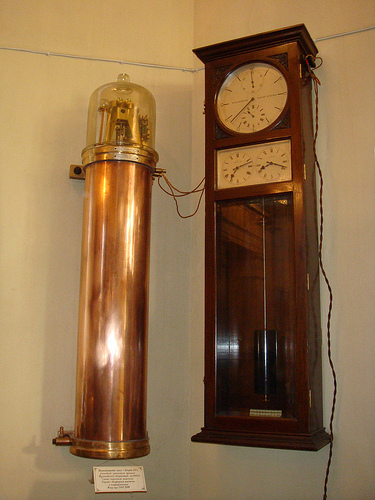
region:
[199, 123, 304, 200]
clock with the roman numeral l on it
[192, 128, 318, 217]
clock with the roman numeral ll on it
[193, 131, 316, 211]
clock with the roman numeral lll on it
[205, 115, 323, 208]
clock with the roman numeral lV on it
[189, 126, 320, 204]
clock with the roman numeral V on it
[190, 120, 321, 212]
clock with the roman numeral Vl on it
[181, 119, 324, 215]
clock with the roman numeral Vll on it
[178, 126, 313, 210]
clock with the roman numeral Vlll on it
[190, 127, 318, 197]
clock with the roman numeral X on it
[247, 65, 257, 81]
black line on device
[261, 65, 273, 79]
black line on device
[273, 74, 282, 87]
black line on device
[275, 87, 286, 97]
black line on device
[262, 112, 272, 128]
black line on device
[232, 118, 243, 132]
black line on device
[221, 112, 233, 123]
black line on device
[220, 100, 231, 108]
black line on device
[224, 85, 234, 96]
black line on device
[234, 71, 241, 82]
black line on device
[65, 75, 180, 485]
a long bronze capsule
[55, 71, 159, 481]
bronze capsule attached to the wall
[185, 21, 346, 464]
an old clock on the wall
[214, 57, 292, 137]
clock is color white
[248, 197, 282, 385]
pendule of the clock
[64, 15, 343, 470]
a machine next a clock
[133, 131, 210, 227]
wires connecting a clock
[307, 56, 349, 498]
a long wire hang from clock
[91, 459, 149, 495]
a white label with letters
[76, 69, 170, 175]
top of machine has a glass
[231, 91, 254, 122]
handle of clock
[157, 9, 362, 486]
clock over a white wall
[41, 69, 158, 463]
old antique copper barometer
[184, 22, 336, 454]
wooden barometer meter case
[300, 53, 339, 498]
twisted thin black wires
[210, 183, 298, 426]
single pane of glass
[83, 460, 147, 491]
white card with black printed words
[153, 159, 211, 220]
three copper coloured wires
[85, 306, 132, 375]
reflection of light off copper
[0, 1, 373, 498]
white painted wall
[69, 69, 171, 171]
transparent glass cap on barometer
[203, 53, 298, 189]
faces displaying pressure, humidity, and time